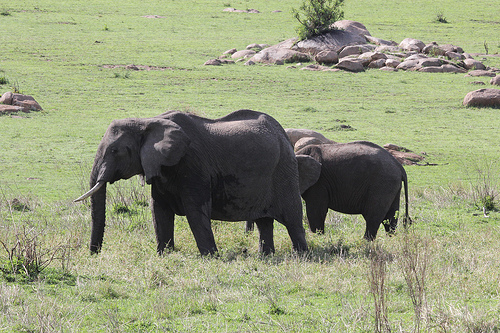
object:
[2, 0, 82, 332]
left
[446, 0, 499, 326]
right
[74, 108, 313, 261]
elephants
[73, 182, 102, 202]
tusk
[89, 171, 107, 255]
trunk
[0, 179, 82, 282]
bush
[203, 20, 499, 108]
rocks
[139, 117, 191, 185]
ears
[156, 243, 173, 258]
feet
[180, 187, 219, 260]
legs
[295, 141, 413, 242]
elephant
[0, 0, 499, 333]
grass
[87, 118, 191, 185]
head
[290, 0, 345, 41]
plant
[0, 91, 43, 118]
rocks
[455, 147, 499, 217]
tuft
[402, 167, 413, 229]
tail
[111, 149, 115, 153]
eye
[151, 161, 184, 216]
chest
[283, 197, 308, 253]
legs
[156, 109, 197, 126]
hump